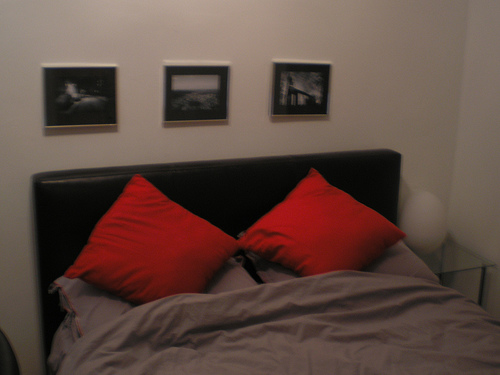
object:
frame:
[39, 60, 122, 135]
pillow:
[62, 173, 242, 307]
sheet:
[58, 250, 420, 347]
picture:
[158, 60, 236, 126]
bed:
[31, 146, 500, 375]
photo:
[36, 66, 119, 135]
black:
[158, 64, 226, 124]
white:
[182, 76, 208, 90]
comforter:
[54, 267, 499, 374]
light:
[398, 187, 447, 251]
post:
[31, 173, 57, 368]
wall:
[0, 0, 500, 236]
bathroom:
[0, 0, 500, 375]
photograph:
[273, 64, 328, 117]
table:
[394, 228, 498, 304]